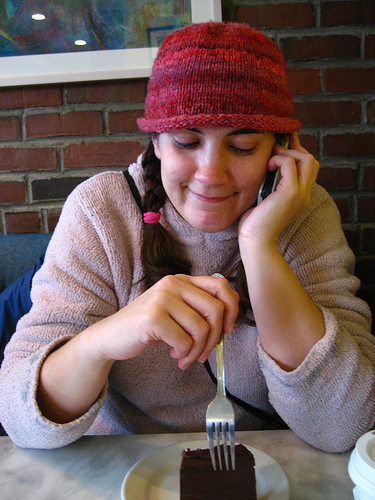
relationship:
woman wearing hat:
[1, 22, 374, 453] [135, 19, 301, 133]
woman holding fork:
[1, 22, 374, 453] [202, 330, 238, 473]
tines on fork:
[205, 422, 239, 473] [202, 330, 238, 473]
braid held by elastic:
[140, 135, 191, 288] [142, 206, 165, 225]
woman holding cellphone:
[1, 22, 374, 453] [256, 128, 293, 209]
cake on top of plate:
[176, 441, 259, 500] [119, 436, 293, 500]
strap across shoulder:
[118, 165, 287, 428] [65, 156, 144, 206]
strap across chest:
[118, 165, 287, 428] [122, 220, 293, 344]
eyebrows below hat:
[185, 122, 268, 140] [135, 19, 301, 133]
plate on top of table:
[119, 436, 293, 500] [0, 422, 374, 499]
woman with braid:
[1, 22, 374, 453] [140, 135, 191, 288]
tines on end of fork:
[205, 422, 239, 473] [202, 330, 238, 473]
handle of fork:
[207, 270, 232, 393] [202, 330, 238, 473]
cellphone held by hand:
[256, 128, 293, 209] [235, 129, 322, 249]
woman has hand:
[1, 22, 374, 453] [235, 129, 322, 249]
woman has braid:
[1, 22, 374, 453] [140, 135, 191, 288]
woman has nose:
[1, 22, 374, 453] [192, 141, 228, 189]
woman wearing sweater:
[1, 22, 374, 453] [2, 150, 373, 452]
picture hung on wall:
[1, 0, 225, 92] [1, 1, 374, 340]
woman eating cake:
[1, 22, 374, 453] [176, 441, 259, 500]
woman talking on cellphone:
[1, 22, 374, 453] [256, 128, 293, 209]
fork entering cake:
[202, 330, 238, 473] [176, 441, 259, 500]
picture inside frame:
[1, 0, 225, 92] [3, 0, 223, 86]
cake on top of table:
[176, 441, 259, 500] [0, 422, 374, 499]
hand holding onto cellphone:
[235, 129, 322, 249] [256, 128, 293, 209]